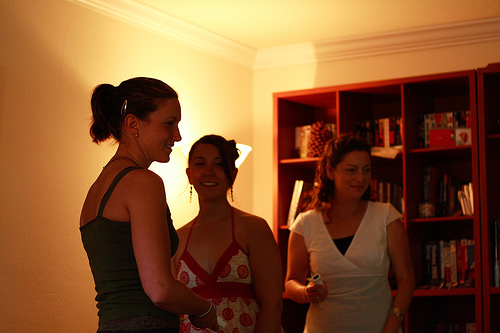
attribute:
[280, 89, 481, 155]
books — large, filled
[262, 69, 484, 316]
shelf — brown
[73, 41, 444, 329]
women — young, wearing, standing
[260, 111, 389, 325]
woman — holding, young, wearing, smiling, standing, holding wii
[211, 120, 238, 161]
hair — barrett, dark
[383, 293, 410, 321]
bracelet — gold, white, silver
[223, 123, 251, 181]
lamp — white, standing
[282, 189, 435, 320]
shirt — white, strap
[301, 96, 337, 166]
cone — pine